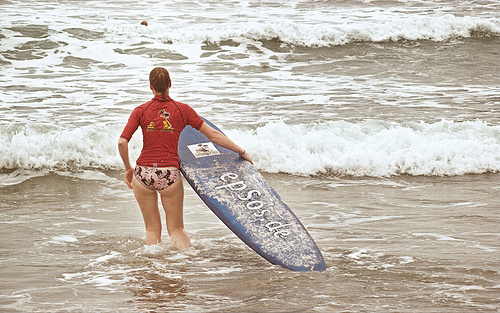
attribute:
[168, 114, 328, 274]
surfboard — blue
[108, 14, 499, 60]
wave — muddy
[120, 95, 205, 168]
shirt — red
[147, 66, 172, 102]
hair — wet, styled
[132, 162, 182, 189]
suit — decorated, colored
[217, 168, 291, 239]
letters — white